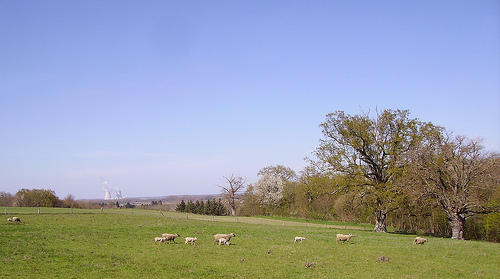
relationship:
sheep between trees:
[407, 226, 435, 255] [222, 103, 498, 241]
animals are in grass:
[152, 212, 436, 252] [3, 203, 497, 276]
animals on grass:
[144, 221, 370, 250] [70, 233, 132, 263]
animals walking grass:
[154, 232, 201, 245] [44, 218, 105, 259]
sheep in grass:
[149, 220, 434, 252] [50, 242, 130, 272]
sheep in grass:
[149, 224, 429, 254] [35, 217, 127, 263]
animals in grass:
[154, 232, 201, 245] [29, 225, 114, 263]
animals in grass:
[154, 232, 201, 245] [28, 235, 139, 276]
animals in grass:
[154, 232, 201, 245] [27, 224, 122, 269]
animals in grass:
[154, 232, 201, 245] [25, 232, 130, 272]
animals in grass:
[154, 232, 201, 245] [16, 226, 128, 266]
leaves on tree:
[383, 127, 403, 143] [426, 122, 482, 236]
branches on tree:
[448, 152, 478, 193] [277, 108, 472, 238]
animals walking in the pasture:
[154, 232, 201, 245] [15, 218, 466, 261]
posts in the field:
[11, 210, 374, 222] [13, 194, 473, 255]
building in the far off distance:
[104, 192, 111, 201] [18, 180, 239, 205]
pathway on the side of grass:
[138, 214, 331, 226] [11, 210, 474, 266]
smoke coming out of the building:
[100, 180, 109, 190] [102, 190, 111, 202]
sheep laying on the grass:
[8, 208, 25, 228] [8, 205, 476, 272]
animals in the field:
[154, 232, 201, 245] [17, 200, 465, 264]